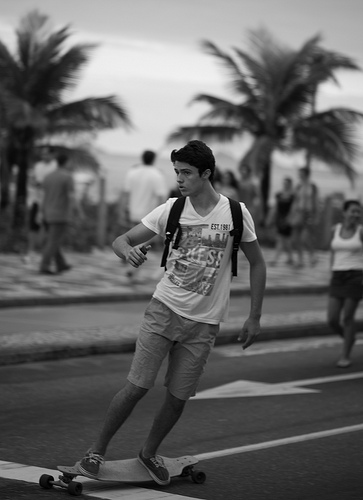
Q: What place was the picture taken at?
A: It was taken at the plain.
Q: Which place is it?
A: It is a plain.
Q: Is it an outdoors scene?
A: Yes, it is outdoors.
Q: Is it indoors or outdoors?
A: It is outdoors.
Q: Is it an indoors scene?
A: No, it is outdoors.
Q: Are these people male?
A: No, they are both male and female.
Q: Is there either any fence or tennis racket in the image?
A: No, there are no fences or rackets.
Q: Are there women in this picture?
A: Yes, there is a woman.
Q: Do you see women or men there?
A: Yes, there is a woman.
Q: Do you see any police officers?
A: No, there are no police officers.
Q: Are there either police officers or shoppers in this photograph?
A: No, there are no police officers or shoppers.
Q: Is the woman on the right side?
A: Yes, the woman is on the right of the image.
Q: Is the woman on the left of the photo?
A: No, the woman is on the right of the image.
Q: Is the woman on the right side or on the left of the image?
A: The woman is on the right of the image.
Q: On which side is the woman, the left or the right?
A: The woman is on the right of the image.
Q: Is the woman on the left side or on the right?
A: The woman is on the right of the image.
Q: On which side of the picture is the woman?
A: The woman is on the right of the image.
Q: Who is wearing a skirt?
A: The woman is wearing a skirt.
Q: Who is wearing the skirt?
A: The woman is wearing a skirt.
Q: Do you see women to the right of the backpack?
A: Yes, there is a woman to the right of the backpack.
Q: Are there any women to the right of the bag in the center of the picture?
A: Yes, there is a woman to the right of the backpack.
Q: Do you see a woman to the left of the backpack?
A: No, the woman is to the right of the backpack.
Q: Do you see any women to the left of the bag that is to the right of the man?
A: No, the woman is to the right of the backpack.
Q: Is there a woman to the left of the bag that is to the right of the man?
A: No, the woman is to the right of the backpack.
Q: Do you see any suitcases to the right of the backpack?
A: No, there is a woman to the right of the backpack.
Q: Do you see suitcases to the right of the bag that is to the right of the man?
A: No, there is a woman to the right of the backpack.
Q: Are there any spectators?
A: No, there are no spectators.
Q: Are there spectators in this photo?
A: No, there are no spectators.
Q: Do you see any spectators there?
A: No, there are no spectators.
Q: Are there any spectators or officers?
A: No, there are no spectators or officers.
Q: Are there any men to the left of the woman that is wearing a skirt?
A: Yes, there is a man to the left of the woman.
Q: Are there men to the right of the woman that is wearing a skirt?
A: No, the man is to the left of the woman.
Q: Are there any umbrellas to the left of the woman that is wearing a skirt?
A: No, there is a man to the left of the woman.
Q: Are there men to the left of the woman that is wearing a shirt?
A: Yes, there is a man to the left of the woman.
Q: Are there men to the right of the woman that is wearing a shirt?
A: No, the man is to the left of the woman.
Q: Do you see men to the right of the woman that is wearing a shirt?
A: No, the man is to the left of the woman.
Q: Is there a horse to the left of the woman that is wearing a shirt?
A: No, there is a man to the left of the woman.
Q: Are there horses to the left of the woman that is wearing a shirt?
A: No, there is a man to the left of the woman.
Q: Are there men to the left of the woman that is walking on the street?
A: Yes, there is a man to the left of the woman.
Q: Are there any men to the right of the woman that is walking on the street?
A: No, the man is to the left of the woman.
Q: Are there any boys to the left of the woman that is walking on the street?
A: No, there is a man to the left of the woman.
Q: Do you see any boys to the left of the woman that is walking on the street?
A: No, there is a man to the left of the woman.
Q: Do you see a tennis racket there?
A: No, there are no rackets.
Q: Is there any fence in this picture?
A: No, there are no fences.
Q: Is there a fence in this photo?
A: No, there are no fences.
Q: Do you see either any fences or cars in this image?
A: No, there are no fences or cars.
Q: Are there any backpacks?
A: Yes, there is a backpack.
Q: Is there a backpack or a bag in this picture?
A: Yes, there is a backpack.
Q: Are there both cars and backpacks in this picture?
A: No, there is a backpack but no cars.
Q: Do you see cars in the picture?
A: No, there are no cars.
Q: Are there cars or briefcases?
A: No, there are no cars or briefcases.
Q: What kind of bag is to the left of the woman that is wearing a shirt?
A: The bag is a backpack.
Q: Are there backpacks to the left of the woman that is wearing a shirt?
A: Yes, there is a backpack to the left of the woman.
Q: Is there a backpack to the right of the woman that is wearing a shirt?
A: No, the backpack is to the left of the woman.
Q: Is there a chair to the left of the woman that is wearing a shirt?
A: No, there is a backpack to the left of the woman.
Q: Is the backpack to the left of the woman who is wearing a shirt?
A: Yes, the backpack is to the left of the woman.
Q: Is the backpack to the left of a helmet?
A: No, the backpack is to the left of the woman.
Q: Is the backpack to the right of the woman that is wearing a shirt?
A: No, the backpack is to the left of the woman.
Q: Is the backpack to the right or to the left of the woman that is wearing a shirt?
A: The backpack is to the left of the woman.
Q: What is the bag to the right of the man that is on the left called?
A: The bag is a backpack.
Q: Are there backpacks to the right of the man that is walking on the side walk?
A: Yes, there is a backpack to the right of the man.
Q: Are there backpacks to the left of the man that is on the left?
A: No, the backpack is to the right of the man.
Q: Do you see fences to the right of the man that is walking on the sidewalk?
A: No, there is a backpack to the right of the man.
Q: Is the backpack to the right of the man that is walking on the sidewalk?
A: Yes, the backpack is to the right of the man.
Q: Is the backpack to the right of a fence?
A: No, the backpack is to the right of the man.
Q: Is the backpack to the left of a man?
A: No, the backpack is to the right of a man.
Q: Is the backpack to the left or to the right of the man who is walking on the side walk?
A: The backpack is to the right of the man.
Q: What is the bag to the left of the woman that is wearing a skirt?
A: The bag is a backpack.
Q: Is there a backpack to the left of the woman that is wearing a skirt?
A: Yes, there is a backpack to the left of the woman.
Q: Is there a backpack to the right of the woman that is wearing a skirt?
A: No, the backpack is to the left of the woman.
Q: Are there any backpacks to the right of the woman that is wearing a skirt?
A: No, the backpack is to the left of the woman.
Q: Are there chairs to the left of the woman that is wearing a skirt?
A: No, there is a backpack to the left of the woman.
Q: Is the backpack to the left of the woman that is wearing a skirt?
A: Yes, the backpack is to the left of the woman.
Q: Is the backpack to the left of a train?
A: No, the backpack is to the left of the woman.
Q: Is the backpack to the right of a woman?
A: No, the backpack is to the left of a woman.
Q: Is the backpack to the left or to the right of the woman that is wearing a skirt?
A: The backpack is to the left of the woman.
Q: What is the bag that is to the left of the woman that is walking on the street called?
A: The bag is a backpack.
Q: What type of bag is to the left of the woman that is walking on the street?
A: The bag is a backpack.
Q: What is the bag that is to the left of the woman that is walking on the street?
A: The bag is a backpack.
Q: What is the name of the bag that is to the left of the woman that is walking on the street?
A: The bag is a backpack.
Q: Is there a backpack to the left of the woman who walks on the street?
A: Yes, there is a backpack to the left of the woman.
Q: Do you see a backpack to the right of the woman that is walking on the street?
A: No, the backpack is to the left of the woman.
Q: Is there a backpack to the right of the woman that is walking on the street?
A: No, the backpack is to the left of the woman.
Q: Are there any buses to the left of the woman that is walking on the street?
A: No, there is a backpack to the left of the woman.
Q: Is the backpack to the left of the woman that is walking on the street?
A: Yes, the backpack is to the left of the woman.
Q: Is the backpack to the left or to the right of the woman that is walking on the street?
A: The backpack is to the left of the woman.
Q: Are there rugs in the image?
A: No, there are no rugs.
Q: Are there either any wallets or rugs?
A: No, there are no rugs or wallets.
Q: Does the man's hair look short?
A: Yes, the hair is short.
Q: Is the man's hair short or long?
A: The hair is short.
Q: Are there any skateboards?
A: Yes, there is a skateboard.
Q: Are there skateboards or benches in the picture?
A: Yes, there is a skateboard.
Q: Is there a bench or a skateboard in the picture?
A: Yes, there is a skateboard.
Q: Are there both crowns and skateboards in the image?
A: No, there is a skateboard but no crowns.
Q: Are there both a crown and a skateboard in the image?
A: No, there is a skateboard but no crowns.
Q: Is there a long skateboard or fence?
A: Yes, there is a long skateboard.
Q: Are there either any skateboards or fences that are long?
A: Yes, the skateboard is long.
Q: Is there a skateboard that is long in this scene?
A: Yes, there is a long skateboard.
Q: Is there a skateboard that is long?
A: Yes, there is a skateboard that is long.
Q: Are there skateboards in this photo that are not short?
A: Yes, there is a long skateboard.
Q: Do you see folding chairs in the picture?
A: No, there are no folding chairs.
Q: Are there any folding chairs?
A: No, there are no folding chairs.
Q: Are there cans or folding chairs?
A: No, there are no folding chairs or cans.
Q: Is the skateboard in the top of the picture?
A: No, the skateboard is in the bottom of the image.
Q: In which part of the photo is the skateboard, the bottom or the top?
A: The skateboard is in the bottom of the image.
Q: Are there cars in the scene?
A: No, there are no cars.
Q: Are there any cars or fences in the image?
A: No, there are no cars or fences.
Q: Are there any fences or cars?
A: No, there are no cars or fences.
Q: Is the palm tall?
A: Yes, the palm is tall.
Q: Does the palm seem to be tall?
A: Yes, the palm is tall.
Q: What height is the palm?
A: The palm is tall.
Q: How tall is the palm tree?
A: The palm tree is tall.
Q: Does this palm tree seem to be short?
A: No, the palm tree is tall.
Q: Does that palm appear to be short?
A: No, the palm is tall.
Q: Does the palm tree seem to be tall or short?
A: The palm tree is tall.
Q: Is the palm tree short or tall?
A: The palm tree is tall.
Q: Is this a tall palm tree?
A: Yes, this is a tall palm tree.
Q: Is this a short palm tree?
A: No, this is a tall palm tree.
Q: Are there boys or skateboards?
A: Yes, there is a skateboard.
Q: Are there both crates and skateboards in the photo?
A: No, there is a skateboard but no crates.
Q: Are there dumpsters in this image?
A: No, there are no dumpsters.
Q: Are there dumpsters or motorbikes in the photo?
A: No, there are no dumpsters or motorbikes.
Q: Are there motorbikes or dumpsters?
A: No, there are no dumpsters or motorbikes.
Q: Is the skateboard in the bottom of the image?
A: Yes, the skateboard is in the bottom of the image.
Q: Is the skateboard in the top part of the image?
A: No, the skateboard is in the bottom of the image.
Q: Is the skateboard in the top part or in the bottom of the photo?
A: The skateboard is in the bottom of the image.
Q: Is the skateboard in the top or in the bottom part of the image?
A: The skateboard is in the bottom of the image.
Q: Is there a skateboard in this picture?
A: Yes, there is a skateboard.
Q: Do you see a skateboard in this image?
A: Yes, there is a skateboard.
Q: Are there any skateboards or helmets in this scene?
A: Yes, there is a skateboard.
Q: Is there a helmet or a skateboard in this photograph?
A: Yes, there is a skateboard.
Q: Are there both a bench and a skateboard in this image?
A: No, there is a skateboard but no benches.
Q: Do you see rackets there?
A: No, there are no rackets.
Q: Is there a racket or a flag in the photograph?
A: No, there are no rackets or flags.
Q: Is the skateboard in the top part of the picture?
A: No, the skateboard is in the bottom of the image.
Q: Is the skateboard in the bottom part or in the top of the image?
A: The skateboard is in the bottom of the image.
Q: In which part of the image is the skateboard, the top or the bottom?
A: The skateboard is in the bottom of the image.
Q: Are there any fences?
A: No, there are no fences.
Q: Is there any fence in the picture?
A: No, there are no fences.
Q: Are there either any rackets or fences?
A: No, there are no fences or rackets.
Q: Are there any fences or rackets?
A: No, there are no fences or rackets.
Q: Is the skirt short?
A: Yes, the skirt is short.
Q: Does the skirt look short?
A: Yes, the skirt is short.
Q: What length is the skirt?
A: The skirt is short.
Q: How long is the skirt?
A: The skirt is short.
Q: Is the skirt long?
A: No, the skirt is short.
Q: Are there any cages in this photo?
A: No, there are no cages.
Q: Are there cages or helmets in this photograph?
A: No, there are no cages or helmets.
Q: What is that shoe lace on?
A: The shoe lace is on the shoe.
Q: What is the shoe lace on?
A: The shoe lace is on the shoe.